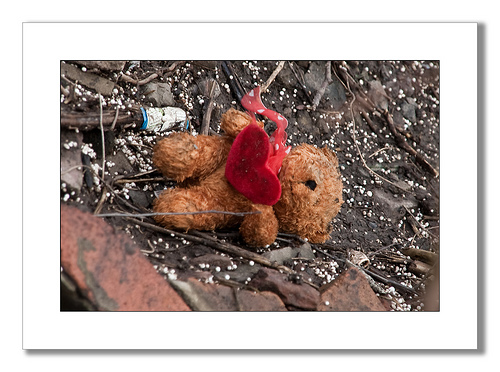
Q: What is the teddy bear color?
A: Brown.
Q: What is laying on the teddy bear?
A: Heart.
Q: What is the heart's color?
A: Red.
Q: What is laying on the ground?
A: Teddy Bear.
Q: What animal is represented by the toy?
A: Bear.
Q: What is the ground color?
A: Grey.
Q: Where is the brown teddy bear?
A: On the ground.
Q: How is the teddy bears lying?
A: On its back.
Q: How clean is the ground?
A: The ground is dirty.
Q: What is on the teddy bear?
A: A red heart.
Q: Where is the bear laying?
A: On the ground.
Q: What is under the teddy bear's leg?
A: A stick.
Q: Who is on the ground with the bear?
A: The bear is alone.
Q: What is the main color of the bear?
A: Brown.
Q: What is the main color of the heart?
A: Red.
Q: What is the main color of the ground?
A: Black.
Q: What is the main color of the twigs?
A: Black.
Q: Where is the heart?
A: On the bear.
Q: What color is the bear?
A: Brown.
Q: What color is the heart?
A: Red.